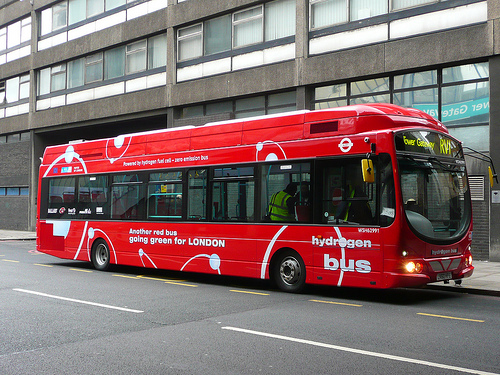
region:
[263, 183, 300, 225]
man in reflective vest inside of a bus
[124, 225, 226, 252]
marketing slogan on side of bus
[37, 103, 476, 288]
red public transit bus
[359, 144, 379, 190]
large rectangular rearview mirror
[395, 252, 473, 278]
bus headlights are on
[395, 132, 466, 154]
electric display on front of bus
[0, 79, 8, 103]
open window on the building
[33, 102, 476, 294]
large red passenger bus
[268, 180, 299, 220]
person wearing a bright yellow vest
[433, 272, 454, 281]
front license plate of bus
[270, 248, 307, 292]
right front tire of bus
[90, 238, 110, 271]
right rear tire of bus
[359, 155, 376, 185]
side mirror of bus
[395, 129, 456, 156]
sign advertising bus route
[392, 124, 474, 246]
large front windshield of bus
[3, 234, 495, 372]
road that bus is driving on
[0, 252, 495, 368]
stripes painted on asphalt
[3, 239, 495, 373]
the road is made of black concrete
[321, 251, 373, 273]
the word bus is in white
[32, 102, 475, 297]
a big parked red bus on the street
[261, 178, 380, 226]
people are inside the bus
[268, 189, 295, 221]
man wearing a neon yellow vest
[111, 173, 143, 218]
a window on the bus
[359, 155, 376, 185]
mirror on the bus is yellow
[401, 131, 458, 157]
head sign on the bus is yellow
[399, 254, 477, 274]
headlights on the bus is on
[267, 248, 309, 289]
a black wheel underneath the bus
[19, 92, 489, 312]
This is a bus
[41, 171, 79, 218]
Window of a bus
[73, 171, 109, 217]
Window of a bus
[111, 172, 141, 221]
Window of a bus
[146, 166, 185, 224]
Window of a bus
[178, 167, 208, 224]
Window of a bus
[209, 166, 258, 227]
Window of a bus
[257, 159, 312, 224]
Window of a bus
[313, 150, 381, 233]
Window of a bus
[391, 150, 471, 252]
Window of a bus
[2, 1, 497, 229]
rows of windows on building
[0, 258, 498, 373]
lines on paved road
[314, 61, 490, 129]
refelction on glass window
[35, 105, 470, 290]
side of red bus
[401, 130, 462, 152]
yellow display on bus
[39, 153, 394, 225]
row of windows on bus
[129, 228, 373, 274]
white words on red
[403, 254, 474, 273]
glowing lights on front of bus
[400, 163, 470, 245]
windshield with curved bottom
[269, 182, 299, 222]
person wearing neon vest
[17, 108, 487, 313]
this is a bus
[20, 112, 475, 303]
the bus is red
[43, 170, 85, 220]
a window on the bus